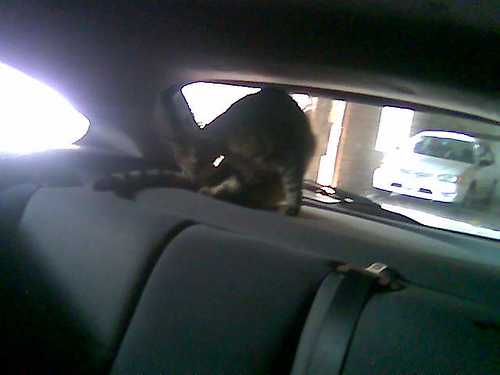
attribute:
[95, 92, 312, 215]
cat —  licking,  washing itself, stripes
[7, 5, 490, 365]
photo — blurry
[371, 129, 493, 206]
car — white, parked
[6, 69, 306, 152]
light — bright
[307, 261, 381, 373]
belt — black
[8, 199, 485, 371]
seats — black, gray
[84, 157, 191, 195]
tail —  long